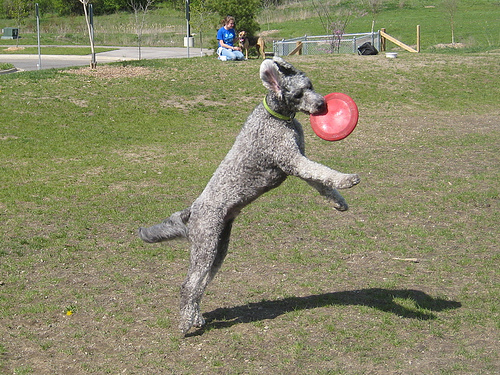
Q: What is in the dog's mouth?
A: Frisbee.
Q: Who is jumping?
A: The dog.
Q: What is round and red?
A: The frisbee.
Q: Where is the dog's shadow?
A: On the grass.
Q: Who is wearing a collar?
A: A dog.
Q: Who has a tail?
A: A dog.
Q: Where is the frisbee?
A: Dogs mouth.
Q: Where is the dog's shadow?
A: Ground under dog.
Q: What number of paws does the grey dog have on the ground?
A: Two.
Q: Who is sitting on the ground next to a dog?
A: Woman in blue shirt.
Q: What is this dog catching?
A: Frisbee.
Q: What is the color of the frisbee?
A: Pink.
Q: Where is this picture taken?
A: Park.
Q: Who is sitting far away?
A: A woman.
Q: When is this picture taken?
A: On a sunny day.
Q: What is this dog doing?
A: Jumping to catch frisbee.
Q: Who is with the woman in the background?
A: A dog.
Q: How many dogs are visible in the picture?
A: Two.